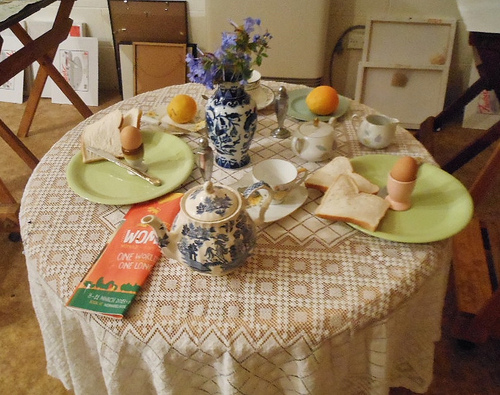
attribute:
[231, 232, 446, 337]
tablecloth — white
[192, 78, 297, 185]
shakers — silver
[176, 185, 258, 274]
tea kettle — white, blue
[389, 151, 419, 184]
egg — brown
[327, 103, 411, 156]
creamer — white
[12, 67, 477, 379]
table — round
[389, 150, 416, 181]
eggs — brown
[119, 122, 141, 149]
eggs — brown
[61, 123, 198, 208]
plate — green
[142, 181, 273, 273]
tea kettle — blue, white